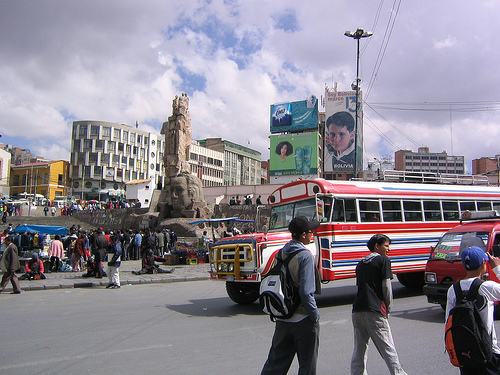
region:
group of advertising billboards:
[262, 86, 370, 173]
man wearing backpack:
[259, 213, 334, 369]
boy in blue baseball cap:
[430, 241, 499, 354]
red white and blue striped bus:
[207, 173, 498, 284]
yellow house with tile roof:
[7, 154, 69, 209]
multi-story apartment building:
[60, 116, 160, 203]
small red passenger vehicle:
[414, 212, 498, 302]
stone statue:
[147, 85, 222, 270]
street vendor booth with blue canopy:
[9, 218, 89, 278]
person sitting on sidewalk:
[125, 248, 183, 280]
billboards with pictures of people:
[256, 81, 371, 178]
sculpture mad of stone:
[151, 87, 222, 232]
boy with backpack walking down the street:
[261, 209, 333, 374]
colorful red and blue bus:
[220, 168, 497, 298]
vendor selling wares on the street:
[5, 210, 90, 275]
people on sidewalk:
[86, 220, 183, 260]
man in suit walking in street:
[2, 233, 29, 300]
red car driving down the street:
[428, 216, 498, 325]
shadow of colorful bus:
[161, 279, 241, 334]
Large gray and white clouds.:
[56, 6, 476, 128]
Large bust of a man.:
[150, 168, 209, 223]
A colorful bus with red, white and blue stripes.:
[234, 178, 495, 285]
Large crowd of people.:
[62, 218, 160, 278]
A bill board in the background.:
[248, 123, 393, 193]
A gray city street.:
[45, 302, 233, 373]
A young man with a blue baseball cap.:
[453, 240, 498, 288]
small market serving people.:
[1, 208, 306, 255]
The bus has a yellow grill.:
[205, 241, 260, 287]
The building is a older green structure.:
[209, 127, 274, 197]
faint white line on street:
[33, 320, 185, 347]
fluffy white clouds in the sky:
[58, 29, 128, 75]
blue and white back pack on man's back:
[208, 249, 305, 320]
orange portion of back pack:
[411, 303, 464, 373]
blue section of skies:
[168, 58, 205, 85]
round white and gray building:
[64, 112, 165, 201]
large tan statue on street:
[143, 82, 230, 184]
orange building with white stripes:
[7, 142, 77, 220]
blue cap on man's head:
[443, 244, 498, 279]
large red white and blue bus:
[280, 156, 466, 328]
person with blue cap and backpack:
[443, 240, 498, 373]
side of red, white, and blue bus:
[322, 180, 356, 280]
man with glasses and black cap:
[285, 213, 322, 248]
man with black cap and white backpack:
[254, 213, 325, 372]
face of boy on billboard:
[323, 108, 363, 165]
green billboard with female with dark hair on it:
[267, 130, 322, 172]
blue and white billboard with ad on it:
[268, 98, 320, 129]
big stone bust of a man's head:
[163, 167, 211, 225]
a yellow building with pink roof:
[12, 160, 70, 198]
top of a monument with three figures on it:
[168, 91, 193, 122]